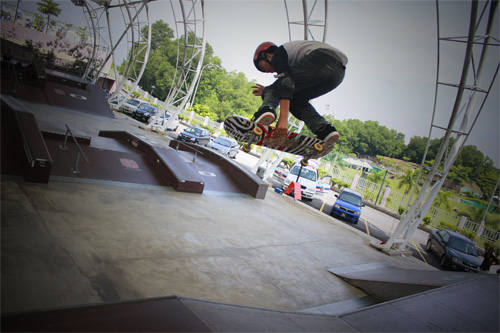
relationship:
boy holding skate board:
[253, 39, 349, 143] [217, 103, 344, 163]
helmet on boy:
[253, 41, 279, 74] [253, 39, 349, 143]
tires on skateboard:
[303, 139, 337, 160] [222, 113, 336, 171]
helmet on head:
[249, 39, 272, 64] [254, 44, 278, 74]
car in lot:
[331, 184, 371, 225] [104, 91, 484, 273]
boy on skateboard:
[253, 39, 350, 143] [193, 91, 424, 198]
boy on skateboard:
[253, 39, 349, 143] [210, 106, 377, 171]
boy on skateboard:
[253, 39, 349, 143] [223, 112, 335, 166]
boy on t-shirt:
[253, 39, 349, 143] [272, 41, 348, 74]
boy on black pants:
[253, 39, 349, 143] [269, 63, 354, 140]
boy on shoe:
[253, 39, 349, 143] [318, 125, 338, 146]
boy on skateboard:
[253, 39, 349, 143] [223, 114, 326, 166]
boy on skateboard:
[253, 39, 349, 143] [237, 115, 329, 158]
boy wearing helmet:
[253, 39, 349, 143] [254, 37, 275, 77]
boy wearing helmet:
[253, 39, 349, 143] [252, 39, 280, 75]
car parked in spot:
[425, 227, 482, 272] [411, 239, 484, 279]